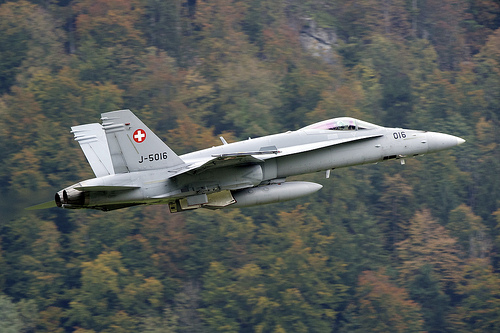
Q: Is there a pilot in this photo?
A: No, there are no pilots.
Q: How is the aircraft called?
A: The aircraft is a jet.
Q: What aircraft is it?
A: The aircraft is a jet.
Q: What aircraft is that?
A: That is a jet.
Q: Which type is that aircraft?
A: That is a jet.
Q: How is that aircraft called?
A: That is a jet.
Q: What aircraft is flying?
A: The aircraft is a jet.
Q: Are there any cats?
A: No, there are no cats.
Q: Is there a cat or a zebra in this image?
A: No, there are no cats or zebras.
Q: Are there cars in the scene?
A: No, there are no cars.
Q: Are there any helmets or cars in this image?
A: No, there are no cars or helmets.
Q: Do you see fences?
A: No, there are no fences.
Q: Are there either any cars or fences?
A: No, there are no fences or cars.